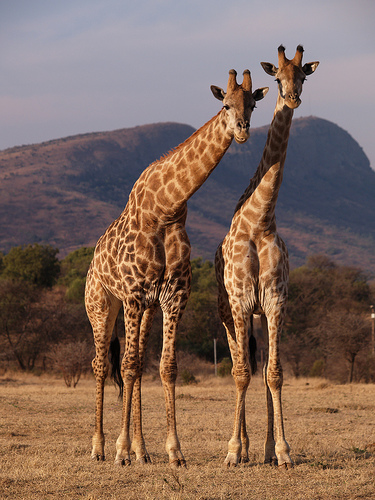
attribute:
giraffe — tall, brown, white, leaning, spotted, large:
[85, 43, 254, 473]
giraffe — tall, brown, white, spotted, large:
[208, 38, 321, 474]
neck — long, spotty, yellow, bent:
[121, 123, 234, 206]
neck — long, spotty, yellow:
[240, 91, 301, 231]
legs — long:
[78, 286, 200, 470]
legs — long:
[210, 305, 319, 474]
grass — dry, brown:
[6, 371, 370, 488]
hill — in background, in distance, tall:
[10, 114, 370, 260]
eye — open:
[220, 104, 239, 115]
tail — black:
[107, 336, 132, 390]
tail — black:
[246, 331, 265, 374]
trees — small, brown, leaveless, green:
[9, 233, 364, 380]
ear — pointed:
[207, 83, 226, 105]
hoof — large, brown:
[169, 449, 192, 468]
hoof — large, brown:
[105, 442, 144, 468]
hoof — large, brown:
[276, 456, 300, 474]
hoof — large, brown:
[219, 446, 248, 470]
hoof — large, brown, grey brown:
[83, 441, 112, 465]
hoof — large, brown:
[133, 451, 154, 468]